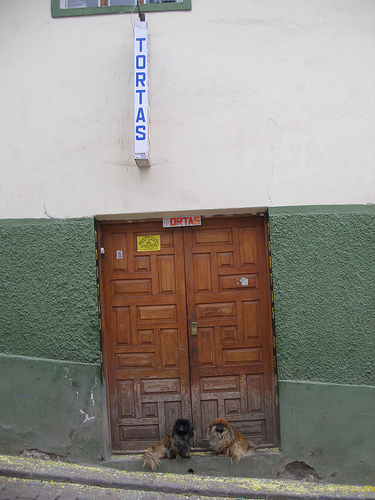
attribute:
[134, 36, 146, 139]
words — blue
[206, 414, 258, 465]
dog — dark brown, sitting, brown, dirty, black, outdoors, small, lying down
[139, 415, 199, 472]
dog — dark brown, sitting, brown, dirty, black, outdoors, small, lying down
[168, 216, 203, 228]
lettering — red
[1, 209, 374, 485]
wall — green, painted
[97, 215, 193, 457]
door — brown, tall, carved, wood, wooden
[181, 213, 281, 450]
door — brown, tall, carved, wood, wooden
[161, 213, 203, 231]
sign — small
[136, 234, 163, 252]
sign — yellow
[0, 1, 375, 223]
building — painted, white